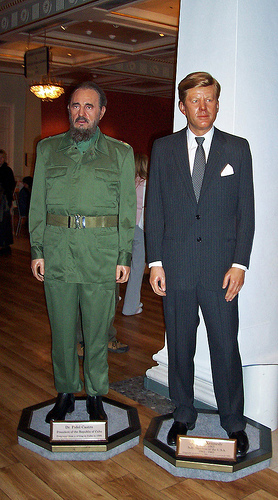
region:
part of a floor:
[116, 466, 135, 482]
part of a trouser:
[179, 411, 189, 423]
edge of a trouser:
[175, 419, 188, 424]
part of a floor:
[111, 472, 132, 497]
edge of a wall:
[151, 388, 163, 397]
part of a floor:
[123, 474, 140, 494]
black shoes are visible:
[47, 379, 101, 437]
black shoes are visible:
[55, 389, 127, 432]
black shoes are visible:
[53, 392, 143, 469]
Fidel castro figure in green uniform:
[27, 79, 137, 451]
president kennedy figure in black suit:
[140, 72, 263, 440]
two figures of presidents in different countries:
[33, 62, 253, 432]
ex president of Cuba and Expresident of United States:
[27, 65, 254, 445]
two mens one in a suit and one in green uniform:
[25, 67, 252, 458]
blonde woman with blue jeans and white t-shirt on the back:
[115, 152, 156, 318]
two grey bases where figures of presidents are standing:
[23, 386, 272, 481]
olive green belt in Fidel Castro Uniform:
[41, 205, 123, 231]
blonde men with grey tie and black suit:
[145, 73, 252, 460]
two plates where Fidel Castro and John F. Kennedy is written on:
[48, 416, 243, 470]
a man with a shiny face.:
[175, 69, 221, 137]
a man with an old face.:
[59, 79, 109, 143]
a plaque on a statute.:
[173, 433, 240, 473]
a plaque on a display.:
[39, 412, 114, 460]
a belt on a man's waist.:
[39, 209, 128, 229]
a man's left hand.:
[220, 266, 247, 301]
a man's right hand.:
[26, 257, 46, 283]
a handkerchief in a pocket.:
[217, 153, 238, 178]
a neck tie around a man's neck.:
[182, 126, 219, 210]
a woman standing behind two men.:
[101, 148, 164, 323]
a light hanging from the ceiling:
[23, 74, 70, 107]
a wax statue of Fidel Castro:
[19, 75, 145, 422]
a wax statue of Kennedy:
[144, 62, 259, 453]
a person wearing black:
[0, 144, 21, 267]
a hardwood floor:
[4, 215, 276, 499]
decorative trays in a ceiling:
[71, 18, 170, 82]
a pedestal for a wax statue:
[141, 401, 275, 480]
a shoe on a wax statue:
[83, 388, 111, 434]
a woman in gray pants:
[121, 142, 158, 317]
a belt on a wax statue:
[40, 205, 124, 232]